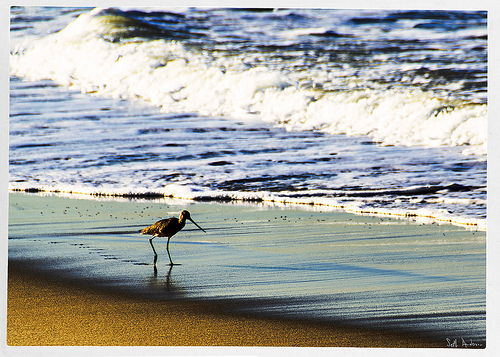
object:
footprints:
[91, 247, 128, 263]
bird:
[139, 209, 206, 270]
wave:
[11, 5, 485, 153]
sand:
[28, 268, 167, 347]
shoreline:
[51, 268, 255, 316]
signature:
[413, 317, 489, 355]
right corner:
[421, 310, 493, 355]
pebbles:
[48, 205, 63, 217]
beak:
[188, 217, 209, 236]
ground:
[202, 193, 466, 241]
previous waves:
[304, 181, 439, 220]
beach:
[191, 250, 467, 336]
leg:
[145, 232, 161, 263]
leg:
[162, 235, 182, 269]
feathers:
[142, 218, 175, 235]